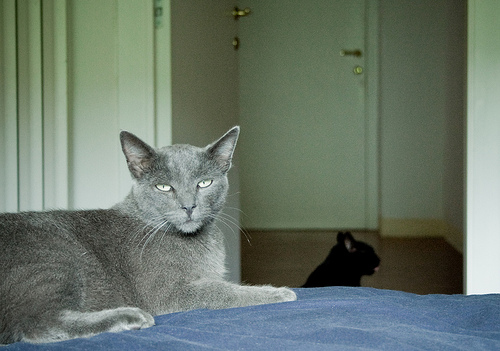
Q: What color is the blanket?
A: Blue.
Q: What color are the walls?
A: White.